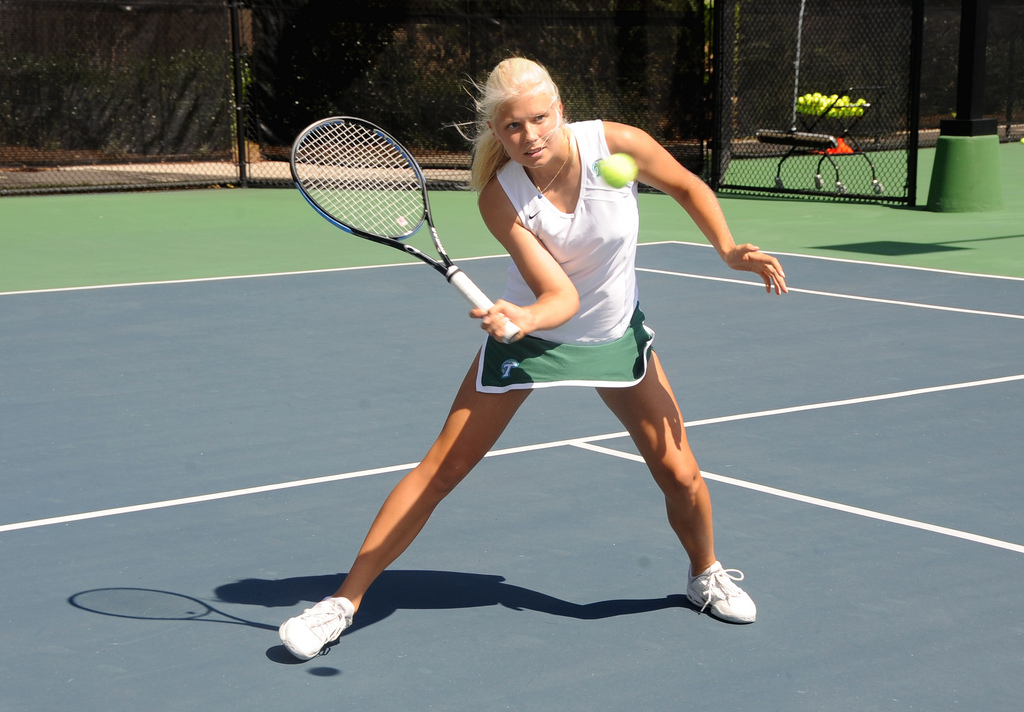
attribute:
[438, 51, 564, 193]
hair — blonde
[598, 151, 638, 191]
tennis ball — green, in air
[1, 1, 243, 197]
fence — black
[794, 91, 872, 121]
tennis balls — stacked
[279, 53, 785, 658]
woman — playing tennis, blonde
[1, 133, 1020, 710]
tennis court — outdoor, green, blue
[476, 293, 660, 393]
skirt — green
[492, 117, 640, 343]
shirt — white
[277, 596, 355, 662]
shoe — white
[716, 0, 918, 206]
fence — black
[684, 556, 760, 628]
sneaker — white